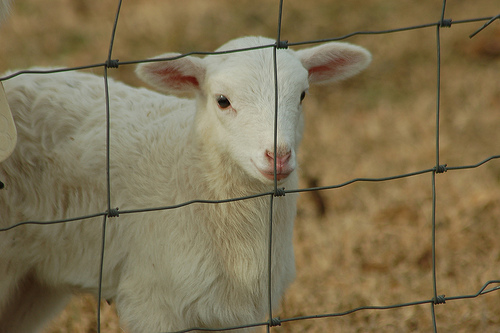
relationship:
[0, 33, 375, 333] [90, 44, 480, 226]
sheep behind fence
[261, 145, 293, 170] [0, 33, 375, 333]
nose on sheep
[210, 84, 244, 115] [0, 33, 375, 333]
eye on sheep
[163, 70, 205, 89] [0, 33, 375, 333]
ear on sheep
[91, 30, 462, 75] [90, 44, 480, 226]
wire on fence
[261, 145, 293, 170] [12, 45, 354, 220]
nose on sheep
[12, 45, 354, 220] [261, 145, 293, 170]
sheep has nose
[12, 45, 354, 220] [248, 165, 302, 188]
sheep has mouth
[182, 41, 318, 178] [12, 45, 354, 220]
head on sheep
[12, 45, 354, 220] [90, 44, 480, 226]
sheep behind fence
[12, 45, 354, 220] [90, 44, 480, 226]
sheep inside fence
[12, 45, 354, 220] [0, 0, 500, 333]
sheep inside fence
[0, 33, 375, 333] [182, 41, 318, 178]
sheep has head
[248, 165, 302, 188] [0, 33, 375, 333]
mouth on sheep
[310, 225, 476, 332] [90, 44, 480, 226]
ground behind fence